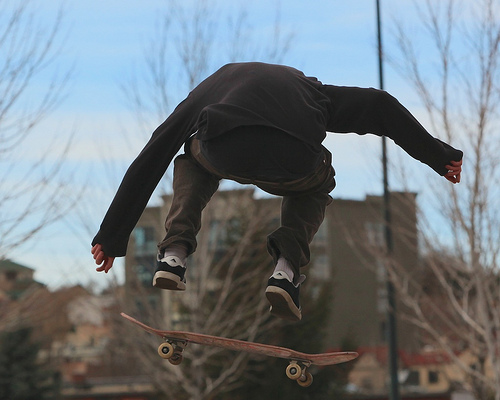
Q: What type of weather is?
A: It is cloudy.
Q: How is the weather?
A: It is cloudy.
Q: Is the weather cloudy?
A: Yes, it is cloudy.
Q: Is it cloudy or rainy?
A: It is cloudy.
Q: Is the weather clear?
A: No, it is cloudy.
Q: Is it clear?
A: No, it is cloudy.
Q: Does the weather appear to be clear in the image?
A: No, it is cloudy.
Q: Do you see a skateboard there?
A: Yes, there is a skateboard.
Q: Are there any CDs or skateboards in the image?
A: Yes, there is a skateboard.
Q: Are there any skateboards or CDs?
A: Yes, there is a skateboard.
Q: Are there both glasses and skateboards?
A: No, there is a skateboard but no glasses.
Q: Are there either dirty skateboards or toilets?
A: Yes, there is a dirty skateboard.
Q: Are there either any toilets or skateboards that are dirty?
A: Yes, the skateboard is dirty.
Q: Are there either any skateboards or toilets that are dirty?
A: Yes, the skateboard is dirty.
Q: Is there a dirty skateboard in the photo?
A: Yes, there is a dirty skateboard.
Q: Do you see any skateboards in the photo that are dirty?
A: Yes, there is a skateboard that is dirty.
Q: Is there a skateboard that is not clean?
A: Yes, there is a dirty skateboard.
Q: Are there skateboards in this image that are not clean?
A: Yes, there is a dirty skateboard.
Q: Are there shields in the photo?
A: No, there are no shields.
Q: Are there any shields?
A: No, there are no shields.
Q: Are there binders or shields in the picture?
A: No, there are no shields or binders.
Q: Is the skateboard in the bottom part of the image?
A: Yes, the skateboard is in the bottom of the image.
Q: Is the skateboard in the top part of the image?
A: No, the skateboard is in the bottom of the image.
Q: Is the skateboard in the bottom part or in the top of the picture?
A: The skateboard is in the bottom of the image.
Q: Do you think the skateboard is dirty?
A: Yes, the skateboard is dirty.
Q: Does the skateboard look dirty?
A: Yes, the skateboard is dirty.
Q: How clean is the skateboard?
A: The skateboard is dirty.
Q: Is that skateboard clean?
A: No, the skateboard is dirty.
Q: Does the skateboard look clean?
A: No, the skateboard is dirty.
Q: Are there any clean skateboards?
A: No, there is a skateboard but it is dirty.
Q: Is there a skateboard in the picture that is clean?
A: No, there is a skateboard but it is dirty.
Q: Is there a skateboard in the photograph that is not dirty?
A: No, there is a skateboard but it is dirty.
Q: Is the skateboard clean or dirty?
A: The skateboard is dirty.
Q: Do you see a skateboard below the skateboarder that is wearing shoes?
A: Yes, there is a skateboard below the skateboarder.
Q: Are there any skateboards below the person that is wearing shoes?
A: Yes, there is a skateboard below the skateboarder.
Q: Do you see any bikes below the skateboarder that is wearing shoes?
A: No, there is a skateboard below the skateboarder.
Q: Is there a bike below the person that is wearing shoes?
A: No, there is a skateboard below the skateboarder.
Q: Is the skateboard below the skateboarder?
A: Yes, the skateboard is below the skateboarder.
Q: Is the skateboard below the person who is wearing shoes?
A: Yes, the skateboard is below the skateboarder.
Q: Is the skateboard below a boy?
A: No, the skateboard is below the skateboarder.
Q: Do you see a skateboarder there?
A: Yes, there is a skateboarder.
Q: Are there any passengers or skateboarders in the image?
A: Yes, there is a skateboarder.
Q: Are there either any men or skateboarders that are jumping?
A: Yes, the skateboarder is jumping.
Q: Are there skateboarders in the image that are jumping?
A: Yes, there is a skateboarder that is jumping.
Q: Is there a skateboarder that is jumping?
A: Yes, there is a skateboarder that is jumping.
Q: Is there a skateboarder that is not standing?
A: Yes, there is a skateboarder that is jumping.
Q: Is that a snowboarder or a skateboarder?
A: That is a skateboarder.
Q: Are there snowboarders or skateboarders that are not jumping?
A: No, there is a skateboarder but he is jumping.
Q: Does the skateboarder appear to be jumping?
A: Yes, the skateboarder is jumping.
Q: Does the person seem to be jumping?
A: Yes, the skateboarder is jumping.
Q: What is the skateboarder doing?
A: The skateboarder is jumping.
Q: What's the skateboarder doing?
A: The skateboarder is jumping.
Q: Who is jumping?
A: The skateboarder is jumping.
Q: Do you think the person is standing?
A: No, the skateboarder is jumping.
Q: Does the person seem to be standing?
A: No, the skateboarder is jumping.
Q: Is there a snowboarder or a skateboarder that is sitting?
A: No, there is a skateboarder but he is jumping.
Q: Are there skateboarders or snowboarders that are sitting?
A: No, there is a skateboarder but he is jumping.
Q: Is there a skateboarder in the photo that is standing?
A: No, there is a skateboarder but he is jumping.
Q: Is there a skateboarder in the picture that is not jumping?
A: No, there is a skateboarder but he is jumping.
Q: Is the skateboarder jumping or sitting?
A: The skateboarder is jumping.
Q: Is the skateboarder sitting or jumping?
A: The skateboarder is jumping.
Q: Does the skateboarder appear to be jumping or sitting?
A: The skateboarder is jumping.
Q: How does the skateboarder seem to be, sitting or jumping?
A: The skateboarder is jumping.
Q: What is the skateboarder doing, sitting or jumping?
A: The skateboarder is jumping.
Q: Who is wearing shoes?
A: The skateboarder is wearing shoes.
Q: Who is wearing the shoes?
A: The skateboarder is wearing shoes.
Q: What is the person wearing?
A: The skateboarder is wearing shoes.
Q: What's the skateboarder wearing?
A: The skateboarder is wearing shoes.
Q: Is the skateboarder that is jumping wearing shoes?
A: Yes, the skateboarder is wearing shoes.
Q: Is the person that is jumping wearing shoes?
A: Yes, the skateboarder is wearing shoes.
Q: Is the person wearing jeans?
A: No, the skateboarder is wearing shoes.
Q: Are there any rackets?
A: No, there are no rackets.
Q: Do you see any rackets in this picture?
A: No, there are no rackets.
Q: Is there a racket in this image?
A: No, there are no rackets.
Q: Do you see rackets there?
A: No, there are no rackets.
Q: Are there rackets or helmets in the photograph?
A: No, there are no rackets or helmets.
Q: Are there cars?
A: No, there are no cars.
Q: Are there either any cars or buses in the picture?
A: No, there are no cars or buses.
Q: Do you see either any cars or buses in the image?
A: No, there are no cars or buses.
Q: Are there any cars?
A: No, there are no cars.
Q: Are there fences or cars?
A: No, there are no cars or fences.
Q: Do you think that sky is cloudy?
A: Yes, the sky is cloudy.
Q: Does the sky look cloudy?
A: Yes, the sky is cloudy.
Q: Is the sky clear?
A: No, the sky is cloudy.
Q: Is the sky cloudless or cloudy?
A: The sky is cloudy.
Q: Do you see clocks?
A: No, there are no clocks.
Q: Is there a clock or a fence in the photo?
A: No, there are no clocks or fences.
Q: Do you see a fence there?
A: No, there are no fences.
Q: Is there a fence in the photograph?
A: No, there are no fences.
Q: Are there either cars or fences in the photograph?
A: No, there are no fences or cars.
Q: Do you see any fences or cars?
A: No, there are no fences or cars.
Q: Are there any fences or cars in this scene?
A: No, there are no fences or cars.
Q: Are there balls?
A: No, there are no balls.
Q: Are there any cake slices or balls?
A: No, there are no balls or cake slices.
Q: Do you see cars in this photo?
A: No, there are no cars.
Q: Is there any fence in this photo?
A: No, there are no fences.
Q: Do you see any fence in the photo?
A: No, there are no fences.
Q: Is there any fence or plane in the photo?
A: No, there are no fences or airplanes.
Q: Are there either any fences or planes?
A: No, there are no fences or planes.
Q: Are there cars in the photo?
A: No, there are no cars.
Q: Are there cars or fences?
A: No, there are no cars or fences.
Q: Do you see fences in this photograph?
A: No, there are no fences.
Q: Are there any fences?
A: No, there are no fences.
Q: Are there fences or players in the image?
A: No, there are no fences or players.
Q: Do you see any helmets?
A: No, there are no helmets.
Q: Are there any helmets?
A: No, there are no helmets.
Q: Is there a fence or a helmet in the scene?
A: No, there are no helmets or fences.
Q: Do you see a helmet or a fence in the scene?
A: No, there are no helmets or fences.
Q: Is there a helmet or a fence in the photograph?
A: No, there are no helmets or fences.